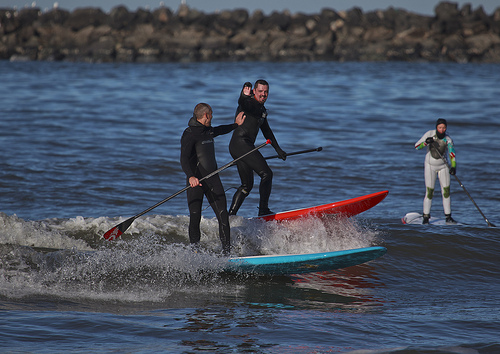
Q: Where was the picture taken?
A: It was taken at the ocean.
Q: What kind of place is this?
A: It is an ocean.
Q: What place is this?
A: It is an ocean.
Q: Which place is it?
A: It is an ocean.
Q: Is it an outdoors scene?
A: Yes, it is outdoors.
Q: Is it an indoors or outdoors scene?
A: It is outdoors.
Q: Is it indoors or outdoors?
A: It is outdoors.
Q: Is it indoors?
A: No, it is outdoors.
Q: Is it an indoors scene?
A: No, it is outdoors.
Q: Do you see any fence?
A: No, there are no fences.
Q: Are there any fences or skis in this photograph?
A: No, there are no fences or skis.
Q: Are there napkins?
A: No, there are no napkins.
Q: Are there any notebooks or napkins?
A: No, there are no napkins or notebooks.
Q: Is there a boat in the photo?
A: No, there are no boats.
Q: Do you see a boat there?
A: No, there are no boats.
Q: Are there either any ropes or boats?
A: No, there are no boats or ropes.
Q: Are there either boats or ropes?
A: No, there are no boats or ropes.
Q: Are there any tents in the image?
A: No, there are no tents.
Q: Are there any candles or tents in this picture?
A: No, there are no tents or candles.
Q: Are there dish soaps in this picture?
A: No, there are no dish soaps.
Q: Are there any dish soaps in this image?
A: No, there are no dish soaps.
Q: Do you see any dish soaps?
A: No, there are no dish soaps.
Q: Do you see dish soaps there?
A: No, there are no dish soaps.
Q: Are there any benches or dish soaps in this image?
A: No, there are no dish soaps or benches.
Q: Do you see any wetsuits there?
A: Yes, there is a wetsuit.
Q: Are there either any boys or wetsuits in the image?
A: Yes, there is a wetsuit.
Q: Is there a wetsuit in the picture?
A: Yes, there is a wetsuit.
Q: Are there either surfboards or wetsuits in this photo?
A: Yes, there is a wetsuit.